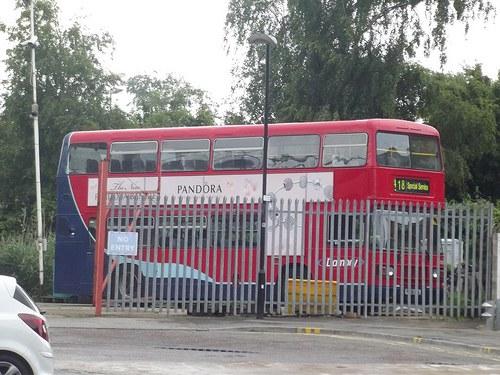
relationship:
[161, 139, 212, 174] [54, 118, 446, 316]
window on side of a bus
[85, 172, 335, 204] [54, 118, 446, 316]
sign on bus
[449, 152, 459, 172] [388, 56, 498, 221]
leaves on trees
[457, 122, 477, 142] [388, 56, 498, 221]
leaves on trees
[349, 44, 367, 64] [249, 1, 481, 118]
leaves on trees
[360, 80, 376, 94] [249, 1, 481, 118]
leaves on trees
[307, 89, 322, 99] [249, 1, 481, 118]
leaves on trees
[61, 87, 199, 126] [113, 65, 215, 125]
leaves on trees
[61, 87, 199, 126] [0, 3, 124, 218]
leaves on trees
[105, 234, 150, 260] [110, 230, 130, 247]
gray sign with white letters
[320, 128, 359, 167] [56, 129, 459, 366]
window on side of bus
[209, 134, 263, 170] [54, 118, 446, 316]
window on side of bus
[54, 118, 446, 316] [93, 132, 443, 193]
bus with decks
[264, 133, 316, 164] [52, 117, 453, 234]
glass window on side of bus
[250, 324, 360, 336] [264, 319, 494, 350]
curb of a sidewalk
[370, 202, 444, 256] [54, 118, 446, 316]
window of a bus